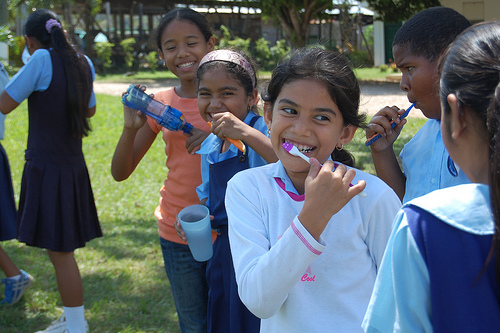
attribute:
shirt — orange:
[135, 80, 210, 232]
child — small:
[176, 55, 268, 330]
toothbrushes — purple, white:
[289, 136, 324, 181]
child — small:
[219, 40, 419, 332]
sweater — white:
[148, 150, 403, 323]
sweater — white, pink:
[231, 172, 401, 326]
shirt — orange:
[142, 87, 211, 242]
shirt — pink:
[223, 159, 400, 329]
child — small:
[360, 16, 497, 330]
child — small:
[224, 43, 403, 330]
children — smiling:
[155, 8, 346, 175]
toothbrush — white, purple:
[232, 123, 340, 184]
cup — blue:
[180, 204, 214, 263]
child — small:
[0, 7, 105, 331]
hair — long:
[53, 45, 85, 100]